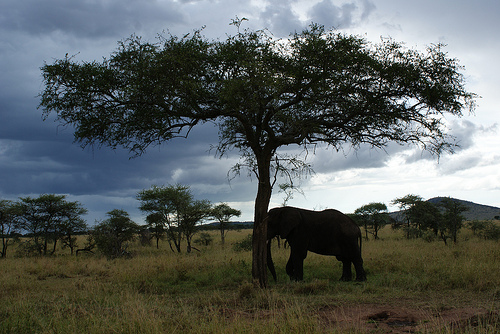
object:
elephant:
[270, 204, 367, 283]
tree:
[31, 34, 482, 287]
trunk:
[250, 152, 276, 277]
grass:
[393, 270, 415, 288]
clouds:
[0, 0, 500, 205]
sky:
[0, 0, 500, 230]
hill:
[466, 209, 484, 220]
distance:
[356, 193, 500, 219]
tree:
[390, 194, 425, 237]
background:
[0, 0, 499, 229]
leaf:
[211, 89, 239, 111]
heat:
[0, 226, 500, 333]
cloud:
[443, 0, 498, 49]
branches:
[111, 42, 154, 75]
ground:
[310, 283, 340, 296]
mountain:
[164, 196, 500, 230]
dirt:
[143, 290, 165, 305]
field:
[273, 280, 419, 334]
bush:
[87, 210, 131, 254]